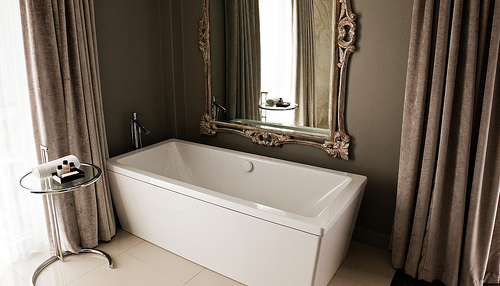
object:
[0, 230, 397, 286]
tiles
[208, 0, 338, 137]
hanging mirror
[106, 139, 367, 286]
bathtub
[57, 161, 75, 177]
small bottles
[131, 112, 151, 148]
fixture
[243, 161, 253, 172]
drain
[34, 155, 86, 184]
contents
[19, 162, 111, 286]
small table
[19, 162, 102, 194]
glass top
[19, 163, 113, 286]
end table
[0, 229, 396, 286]
floor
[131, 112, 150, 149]
faucet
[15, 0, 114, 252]
curtain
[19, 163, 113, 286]
table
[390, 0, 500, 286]
drape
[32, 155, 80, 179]
towel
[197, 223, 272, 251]
white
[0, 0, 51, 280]
window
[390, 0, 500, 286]
curtain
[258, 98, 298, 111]
reflection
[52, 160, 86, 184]
toiletries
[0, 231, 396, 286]
tiling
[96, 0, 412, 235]
wall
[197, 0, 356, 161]
frame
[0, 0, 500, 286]
bathroom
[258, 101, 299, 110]
table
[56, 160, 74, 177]
shampoo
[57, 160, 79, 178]
objects